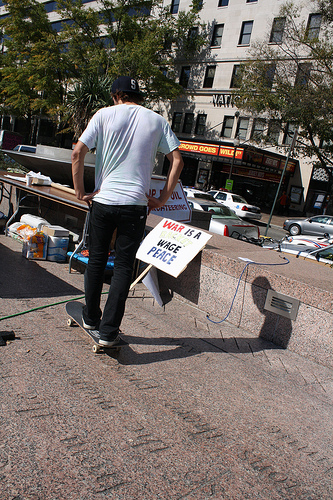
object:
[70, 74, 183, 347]
man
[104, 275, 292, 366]
shadow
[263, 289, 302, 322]
grate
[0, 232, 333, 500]
ground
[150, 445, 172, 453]
prints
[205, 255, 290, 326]
hose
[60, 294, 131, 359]
skateboard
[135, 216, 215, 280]
sign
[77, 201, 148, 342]
jeans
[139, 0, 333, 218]
building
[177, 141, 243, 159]
sign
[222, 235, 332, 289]
wall edge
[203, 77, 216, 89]
black windows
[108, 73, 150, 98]
baseball cap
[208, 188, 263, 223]
police car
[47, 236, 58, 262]
paper towels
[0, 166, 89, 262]
table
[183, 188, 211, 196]
hood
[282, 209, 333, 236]
car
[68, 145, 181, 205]
hands on hips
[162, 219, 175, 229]
letters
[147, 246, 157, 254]
letters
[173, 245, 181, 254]
letters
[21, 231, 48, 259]
packaging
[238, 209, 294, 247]
roadway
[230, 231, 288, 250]
bicycle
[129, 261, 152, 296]
pole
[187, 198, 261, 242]
car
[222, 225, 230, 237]
brake lights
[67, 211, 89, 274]
legs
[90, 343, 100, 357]
wheels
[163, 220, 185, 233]
word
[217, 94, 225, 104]
letters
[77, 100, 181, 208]
t-shirt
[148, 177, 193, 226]
sign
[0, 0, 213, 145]
trees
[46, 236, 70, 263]
containers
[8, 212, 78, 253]
storage